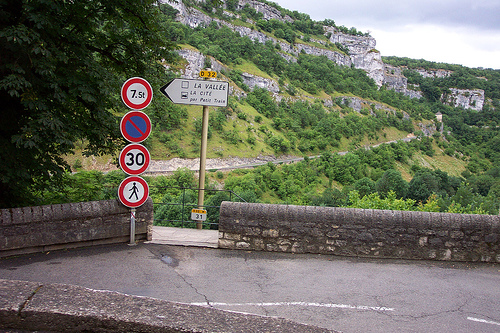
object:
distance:
[7, 4, 497, 110]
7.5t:
[131, 88, 146, 99]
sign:
[120, 77, 153, 110]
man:
[129, 182, 141, 200]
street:
[9, 242, 495, 325]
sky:
[348, 0, 497, 64]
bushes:
[252, 115, 264, 123]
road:
[155, 153, 330, 170]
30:
[126, 152, 144, 167]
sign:
[119, 143, 152, 175]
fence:
[222, 203, 497, 264]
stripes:
[191, 297, 393, 312]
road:
[31, 246, 493, 329]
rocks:
[215, 160, 232, 167]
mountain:
[188, 0, 423, 100]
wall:
[216, 199, 493, 260]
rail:
[152, 186, 231, 227]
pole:
[129, 204, 136, 243]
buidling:
[432, 111, 444, 130]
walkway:
[150, 224, 218, 248]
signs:
[120, 175, 149, 206]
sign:
[160, 79, 228, 106]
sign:
[118, 111, 154, 142]